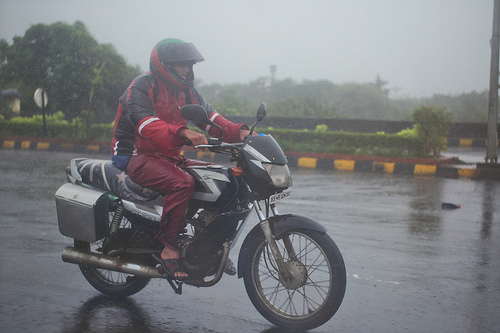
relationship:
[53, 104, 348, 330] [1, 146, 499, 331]
motorcycle on road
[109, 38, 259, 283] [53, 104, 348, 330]
man riding motorcycle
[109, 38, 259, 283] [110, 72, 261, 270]
man wearing red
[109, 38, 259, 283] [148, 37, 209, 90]
man wearing a helmet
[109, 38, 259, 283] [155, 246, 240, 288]
man wearing sandals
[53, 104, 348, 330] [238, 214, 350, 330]
motorcycle has front wheel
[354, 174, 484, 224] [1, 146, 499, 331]
rain on road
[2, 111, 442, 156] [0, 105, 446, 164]
leaves are on hedge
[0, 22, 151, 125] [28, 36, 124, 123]
trees have leaves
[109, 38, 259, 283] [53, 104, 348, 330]
man on motorcycle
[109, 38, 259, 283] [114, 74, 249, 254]
man wearing a suit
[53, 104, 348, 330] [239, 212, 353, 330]
motorcycle has a front wheel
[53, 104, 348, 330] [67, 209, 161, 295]
motorcycle has a rear wheel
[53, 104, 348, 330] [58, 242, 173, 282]
motorcycle has an exhaust pipe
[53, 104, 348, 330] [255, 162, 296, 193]
motorcycle has a headlight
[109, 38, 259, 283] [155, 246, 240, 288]
man has on sandals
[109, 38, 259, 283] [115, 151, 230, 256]
man wearing pants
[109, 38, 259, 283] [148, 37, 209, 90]
man has on a helmet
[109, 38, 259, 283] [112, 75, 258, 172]
man wearing a jacket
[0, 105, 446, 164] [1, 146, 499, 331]
hedge lines road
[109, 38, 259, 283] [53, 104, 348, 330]
man riding a motorcycle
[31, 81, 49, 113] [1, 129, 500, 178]
sign on curb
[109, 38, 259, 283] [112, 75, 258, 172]
man wearing jacket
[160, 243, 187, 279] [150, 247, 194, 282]
foot in sandal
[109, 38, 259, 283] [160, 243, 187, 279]
man has a foot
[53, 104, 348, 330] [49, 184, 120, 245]
motorcycle has a storage compartment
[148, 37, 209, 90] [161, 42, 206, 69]
helmet has a visor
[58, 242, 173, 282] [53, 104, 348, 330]
exhaust pipe on motorcycle